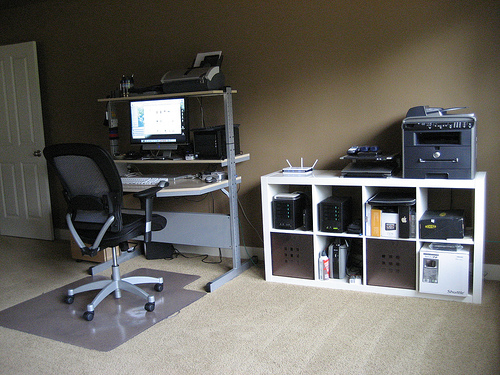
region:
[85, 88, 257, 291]
a gray desk against a wall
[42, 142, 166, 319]
a black and silver swiveling chair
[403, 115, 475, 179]
a gray stereo on an entertainment unit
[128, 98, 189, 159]
a computer monitor on a desk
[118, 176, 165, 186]
a white keyboard on a desk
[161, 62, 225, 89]
a printer on a shelf of a desk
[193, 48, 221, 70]
a sheet of paper on a printer's tray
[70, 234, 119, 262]
a wooden box on the floor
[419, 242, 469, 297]
a white cardboard box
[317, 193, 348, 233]
a black speaker inside an entertainment unit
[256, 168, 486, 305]
white cupboard with boxes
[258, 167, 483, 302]
boxes inside shelf container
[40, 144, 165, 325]
office chair infront of desk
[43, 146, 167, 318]
office chair is black and grey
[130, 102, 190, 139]
monitor on top of desk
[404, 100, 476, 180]
printer on shelf unit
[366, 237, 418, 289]
brown boxes inside shelf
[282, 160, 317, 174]
router on top of shelf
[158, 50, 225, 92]
printer on top of desk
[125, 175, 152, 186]
the keyboard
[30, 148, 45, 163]
the door knob on the door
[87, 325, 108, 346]
a mat on the carpet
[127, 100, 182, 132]
a computer screen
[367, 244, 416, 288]
a brown box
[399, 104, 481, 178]
A fax machine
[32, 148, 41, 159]
Doorknob on a white door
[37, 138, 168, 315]
A rolling chair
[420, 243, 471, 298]
A white box in a cupboard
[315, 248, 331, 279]
Whipped cream container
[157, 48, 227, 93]
A regular printer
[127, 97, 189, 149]
A computer monitor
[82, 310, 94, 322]
Wheel on a chair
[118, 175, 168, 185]
A white keyboard on a desk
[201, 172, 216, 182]
A black and gray computer mouse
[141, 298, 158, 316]
Wheel of a chair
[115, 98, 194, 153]
computer monitor on the desk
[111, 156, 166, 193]
white keyboard on the desk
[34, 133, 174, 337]
chair in front of the desk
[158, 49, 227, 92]
printer on the desk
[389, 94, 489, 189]
printer of the shelf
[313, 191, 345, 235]
server in the shelf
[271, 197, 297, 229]
server in the shelf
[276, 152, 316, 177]
router on the desk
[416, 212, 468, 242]
paper on the desk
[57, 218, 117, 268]
box on the floor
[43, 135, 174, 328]
black computer chair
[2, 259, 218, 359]
clear plastic floor protector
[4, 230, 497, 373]
tan carpeted floor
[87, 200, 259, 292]
silver metal bottom of desk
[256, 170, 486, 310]
white horizontal book shelf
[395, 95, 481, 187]
gray and silver printer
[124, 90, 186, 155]
bright computer monitor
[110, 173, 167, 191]
white computer keyboard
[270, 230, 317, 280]
brown plastic storage box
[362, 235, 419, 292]
brown plastic storage box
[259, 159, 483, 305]
a set of shelves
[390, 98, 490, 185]
a black printer on the shelf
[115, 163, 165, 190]
keyboard on the desk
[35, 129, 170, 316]
chair at the desk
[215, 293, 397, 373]
carpet on the floor